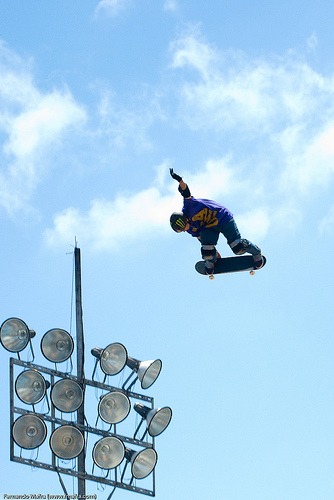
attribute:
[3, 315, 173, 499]
rows of light — angled, big, round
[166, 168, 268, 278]
skateboarder — reaching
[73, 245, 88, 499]
pole — grey, tall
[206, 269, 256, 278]
wheels — red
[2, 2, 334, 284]
clouds — high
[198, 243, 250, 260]
knee pads — silver, black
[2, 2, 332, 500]
air — blue, clear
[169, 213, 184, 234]
helmet — black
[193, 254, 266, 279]
skateboard — blue, yellow, black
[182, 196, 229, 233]
shirt — blue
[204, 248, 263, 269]
shoes — black, white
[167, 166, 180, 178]
glove — black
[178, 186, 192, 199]
armband — black